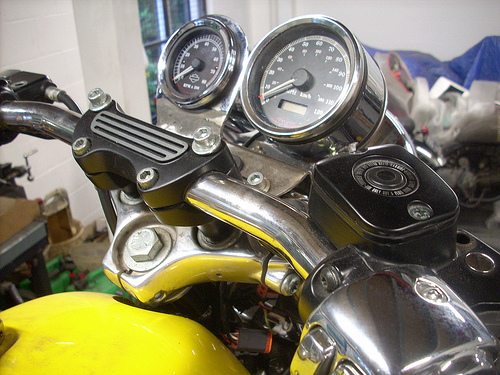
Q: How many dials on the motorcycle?
A: 2.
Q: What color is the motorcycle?
A: Yellow.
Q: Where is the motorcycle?
A: In a garage.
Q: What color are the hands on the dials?
A: White.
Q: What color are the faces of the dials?
A: Black.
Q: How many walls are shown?
A: 2.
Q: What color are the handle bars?
A: Silver.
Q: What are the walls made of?
A: Cinderblocks.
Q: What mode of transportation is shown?
A: Motorcycle.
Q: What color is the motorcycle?
A: Yellow.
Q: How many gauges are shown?
A: 2.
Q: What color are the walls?
A: White.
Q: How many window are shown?
A: 1.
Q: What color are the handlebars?
A: Silver.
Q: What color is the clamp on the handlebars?
A: Black.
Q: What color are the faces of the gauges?
A: Black.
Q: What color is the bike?
A: Yellow.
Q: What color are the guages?
A: Black.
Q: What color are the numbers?
A: White.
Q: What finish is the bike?
A: Chrome.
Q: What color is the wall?
A: White.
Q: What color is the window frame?
A: White.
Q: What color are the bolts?
A: Gray.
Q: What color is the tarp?
A: Blue.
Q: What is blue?
A: The tarp.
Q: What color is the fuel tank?
A: Yellow.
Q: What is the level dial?
A: A rev counter.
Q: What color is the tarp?
A: Blue.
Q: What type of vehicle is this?
A: A motorcycle.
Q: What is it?
A: Bike.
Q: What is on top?
A: Gauges.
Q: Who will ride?
A: Bikers.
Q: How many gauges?
A: 2.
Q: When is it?
A: Day time.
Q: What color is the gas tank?
A: Yellow.